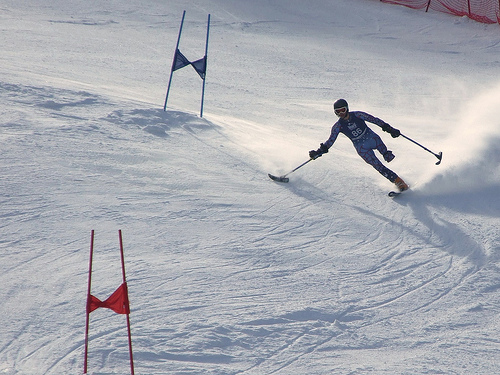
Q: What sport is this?
A: Skiing.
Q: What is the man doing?
A: Skiing.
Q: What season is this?
A: Winter.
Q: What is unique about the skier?
A: He has one leg.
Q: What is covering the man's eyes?
A: Goggles.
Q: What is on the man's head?
A: Helmet.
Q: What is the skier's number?
A: 86.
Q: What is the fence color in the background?
A: Orange.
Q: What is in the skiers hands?
A: Ski poles.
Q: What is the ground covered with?
A: Snow.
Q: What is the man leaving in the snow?
A: Ski tracks.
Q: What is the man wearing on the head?
A: Helmet.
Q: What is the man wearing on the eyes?
A: Glasses.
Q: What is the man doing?
A: Skiing.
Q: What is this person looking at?
A: The obstacle.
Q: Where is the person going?
A: Downhill.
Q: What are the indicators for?
A: Obstacles.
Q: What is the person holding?
A: Ski poles.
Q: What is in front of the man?
A: A flag.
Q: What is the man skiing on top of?
A: Snow.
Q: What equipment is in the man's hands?
A: Ski poles.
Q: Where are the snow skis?
A: On the man's feet.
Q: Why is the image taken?
A: Remembrance.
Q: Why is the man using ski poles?
A: To increase speed and balance.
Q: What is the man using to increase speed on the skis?
A: Ski poles.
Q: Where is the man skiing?
A: Skiing Tournament.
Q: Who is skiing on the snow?
A: Male competitor.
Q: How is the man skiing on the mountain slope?
A: Snow-skis.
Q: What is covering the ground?
A: Snow.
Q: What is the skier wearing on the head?
A: Helmet.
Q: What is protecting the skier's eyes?
A: Goggles.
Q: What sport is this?
A: Skiing.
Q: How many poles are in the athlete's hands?
A: Two.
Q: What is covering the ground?
A: Snow.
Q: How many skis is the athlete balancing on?
A: One.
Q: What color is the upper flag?
A: Blue.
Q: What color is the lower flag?
A: Red.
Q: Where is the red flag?
A: Lower left corner.